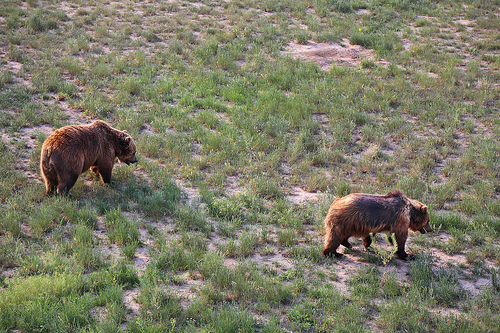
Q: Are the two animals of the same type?
A: Yes, all the animals are bears.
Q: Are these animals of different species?
A: No, all the animals are bears.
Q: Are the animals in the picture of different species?
A: No, all the animals are bears.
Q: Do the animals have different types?
A: No, all the animals are bears.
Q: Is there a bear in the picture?
A: Yes, there is a bear.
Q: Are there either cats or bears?
A: Yes, there is a bear.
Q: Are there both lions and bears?
A: No, there is a bear but no lions.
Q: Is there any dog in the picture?
A: No, there are no dogs.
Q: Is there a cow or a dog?
A: No, there are no dogs or cows.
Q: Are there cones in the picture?
A: No, there are no cones.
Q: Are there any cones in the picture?
A: No, there are no cones.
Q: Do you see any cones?
A: No, there are no cones.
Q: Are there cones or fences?
A: No, there are no cones or fences.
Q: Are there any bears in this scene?
A: Yes, there is a bear.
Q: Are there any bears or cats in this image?
A: Yes, there is a bear.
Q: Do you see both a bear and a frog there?
A: No, there is a bear but no frogs.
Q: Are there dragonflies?
A: No, there are no dragonflies.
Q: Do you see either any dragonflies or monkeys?
A: No, there are no dragonflies or monkeys.